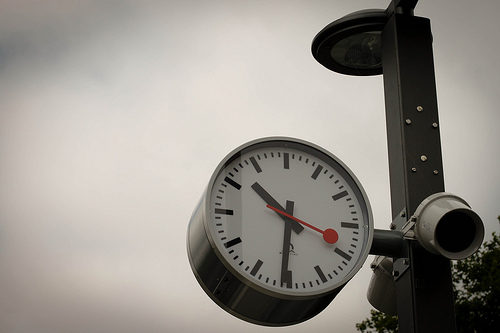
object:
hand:
[265, 204, 339, 244]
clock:
[184, 136, 376, 327]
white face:
[209, 145, 366, 293]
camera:
[408, 191, 486, 262]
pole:
[377, 0, 458, 333]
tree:
[352, 216, 499, 333]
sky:
[0, 0, 500, 333]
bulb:
[309, 7, 388, 78]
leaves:
[453, 271, 457, 276]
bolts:
[417, 106, 424, 112]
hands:
[249, 181, 305, 236]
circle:
[322, 228, 339, 245]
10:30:
[209, 147, 367, 292]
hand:
[279, 200, 295, 288]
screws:
[400, 211, 406, 218]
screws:
[420, 155, 428, 161]